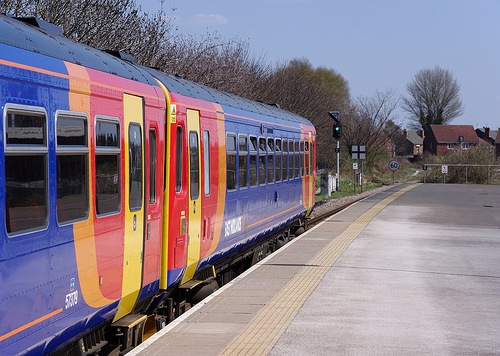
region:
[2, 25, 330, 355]
Red, blue, yellow, orange, and red train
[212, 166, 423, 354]
Yellow caution line next to train tracks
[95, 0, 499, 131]
Sky completely free of clouds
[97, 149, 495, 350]
Ground covered in cement near train tracks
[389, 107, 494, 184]
Two houses side by side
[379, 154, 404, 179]
Sign saying route 60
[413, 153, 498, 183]
Chain link aluminum fence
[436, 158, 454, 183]
White sign hanging on fence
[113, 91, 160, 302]
Doors of the train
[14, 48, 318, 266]
blue red orange and yellow train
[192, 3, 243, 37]
white clouds in blue sky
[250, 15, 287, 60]
white clouds in blue sky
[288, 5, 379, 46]
white clouds in blue sky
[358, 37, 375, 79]
white clouds in blue sky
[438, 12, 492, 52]
white clouds in blue sky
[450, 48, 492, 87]
white clouds in blue sky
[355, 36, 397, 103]
white clouds in blue sky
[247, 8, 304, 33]
white clouds in blue sky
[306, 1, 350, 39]
white clouds in blue sky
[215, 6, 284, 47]
white clouds in blue sky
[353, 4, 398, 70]
white clouds in blue sky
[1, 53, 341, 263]
colorful train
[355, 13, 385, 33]
white clouds in blue sky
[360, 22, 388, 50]
white clouds in blue sky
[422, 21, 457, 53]
white clouds in blue sky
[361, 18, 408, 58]
white clouds in blue sky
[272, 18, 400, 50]
white clouds in blue sky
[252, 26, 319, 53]
white clouds in blue sky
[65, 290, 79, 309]
The number of the train car.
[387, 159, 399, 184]
A sign that says 60 beside the tracks.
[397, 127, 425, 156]
A house in the background.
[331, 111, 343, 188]
A railroad light with a green light lit.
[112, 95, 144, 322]
A door to the railroad cart.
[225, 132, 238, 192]
A window to the railroad cart.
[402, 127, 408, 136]
The chimney on top of a house.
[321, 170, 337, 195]
A power box beside the railroad track.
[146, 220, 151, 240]
The handle to the door.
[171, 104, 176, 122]
A sticker on the side of the cart.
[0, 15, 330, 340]
A train at the platform.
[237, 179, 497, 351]
An empty train platform.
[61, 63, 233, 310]
Red, orange and yellow around the train doors.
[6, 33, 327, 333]
The train is mostly blue.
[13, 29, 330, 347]
A passenger train at a platform.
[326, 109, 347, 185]
The light on the post is green.